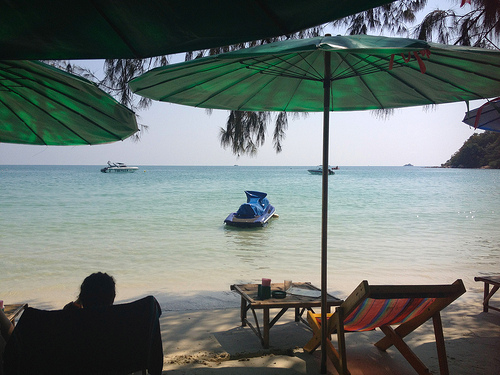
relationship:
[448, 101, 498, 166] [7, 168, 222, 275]
cliff near water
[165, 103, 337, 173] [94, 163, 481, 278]
sky over ocean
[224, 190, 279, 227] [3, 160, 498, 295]
boat in water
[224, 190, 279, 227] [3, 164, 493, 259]
boat in ocean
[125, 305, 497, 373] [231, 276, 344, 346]
beach on table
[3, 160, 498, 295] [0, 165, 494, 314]
water in ocean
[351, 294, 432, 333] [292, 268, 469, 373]
fabric on chair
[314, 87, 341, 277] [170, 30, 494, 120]
pole under umbrella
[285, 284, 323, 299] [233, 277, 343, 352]
paper on table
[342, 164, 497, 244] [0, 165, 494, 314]
waves on ocean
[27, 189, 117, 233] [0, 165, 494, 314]
wave on ocean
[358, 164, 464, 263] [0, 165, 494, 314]
waves on ocean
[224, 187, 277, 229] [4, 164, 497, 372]
boat in water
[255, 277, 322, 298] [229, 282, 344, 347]
items on table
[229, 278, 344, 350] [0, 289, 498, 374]
table on beach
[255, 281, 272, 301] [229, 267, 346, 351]
cup on table